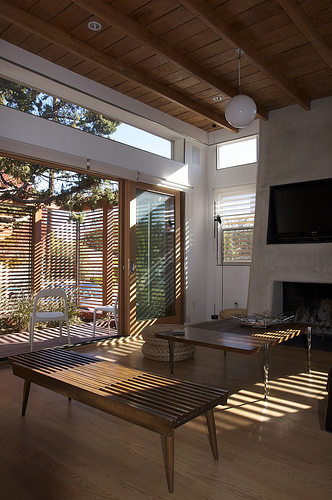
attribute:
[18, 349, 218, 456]
bench — wooden, brown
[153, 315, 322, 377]
table — wooden, brown, long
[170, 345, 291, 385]
legs — brown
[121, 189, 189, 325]
door — large, brown, glass, wooden, open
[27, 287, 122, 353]
chairs — white, plastic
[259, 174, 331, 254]
tv — black, large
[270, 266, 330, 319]
fireplace — opening, woodburning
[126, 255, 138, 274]
handle — black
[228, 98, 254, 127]
globe — white, hanging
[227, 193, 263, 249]
blinds — open, white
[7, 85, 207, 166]
window — rectangular, long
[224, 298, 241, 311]
outlet — white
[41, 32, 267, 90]
beam — brown, wooden, long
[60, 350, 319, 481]
floor — brown, hardwood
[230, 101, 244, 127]
bulb — white, large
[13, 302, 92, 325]
grass — green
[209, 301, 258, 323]
basket — wicker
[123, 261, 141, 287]
lock — black, rounded